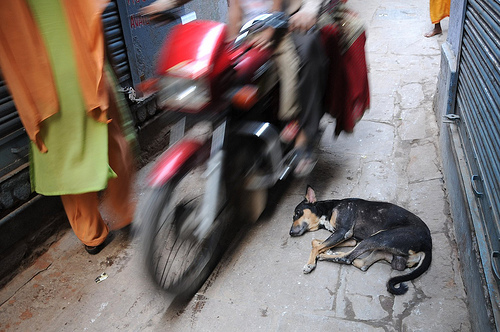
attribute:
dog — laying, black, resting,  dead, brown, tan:
[289, 184, 433, 298]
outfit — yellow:
[0, 0, 137, 257]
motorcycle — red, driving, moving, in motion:
[136, 9, 371, 313]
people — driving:
[139, 0, 343, 181]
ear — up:
[304, 184, 319, 204]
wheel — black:
[139, 142, 232, 302]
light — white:
[159, 75, 212, 110]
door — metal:
[454, 0, 499, 331]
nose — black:
[290, 229, 294, 235]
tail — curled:
[386, 248, 433, 296]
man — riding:
[137, 0, 338, 178]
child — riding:
[223, 0, 303, 144]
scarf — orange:
[0, 0, 114, 153]